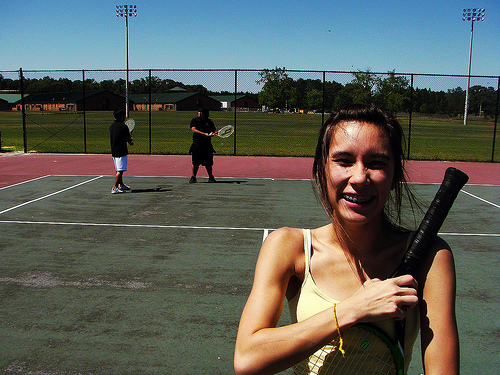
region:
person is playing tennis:
[98, 103, 145, 198]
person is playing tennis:
[196, 102, 249, 189]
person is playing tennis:
[280, 98, 462, 373]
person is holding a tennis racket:
[85, 105, 150, 186]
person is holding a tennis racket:
[190, 101, 242, 197]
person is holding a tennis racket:
[299, 110, 427, 367]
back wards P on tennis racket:
[215, 121, 237, 148]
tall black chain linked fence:
[266, 62, 313, 159]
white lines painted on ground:
[66, 209, 183, 249]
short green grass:
[252, 120, 286, 147]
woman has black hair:
[353, 108, 377, 118]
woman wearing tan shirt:
[306, 300, 315, 315]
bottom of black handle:
[440, 164, 472, 187]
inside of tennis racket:
[348, 359, 363, 373]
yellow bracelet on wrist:
[328, 303, 343, 333]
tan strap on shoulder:
[300, 223, 316, 270]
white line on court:
[175, 213, 203, 238]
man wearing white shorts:
[114, 159, 128, 171]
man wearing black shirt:
[112, 139, 122, 150]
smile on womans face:
[338, 188, 383, 212]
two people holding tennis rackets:
[69, 93, 249, 205]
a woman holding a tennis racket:
[251, 108, 460, 373]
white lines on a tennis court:
[0, 208, 257, 232]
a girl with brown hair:
[298, 90, 404, 247]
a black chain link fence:
[255, 51, 320, 171]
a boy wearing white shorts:
[107, 148, 134, 179]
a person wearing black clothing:
[191, 93, 220, 184]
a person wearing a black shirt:
[105, 116, 135, 153]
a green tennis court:
[30, 198, 250, 325]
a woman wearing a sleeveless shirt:
[262, 226, 384, 334]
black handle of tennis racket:
[382, 168, 474, 276]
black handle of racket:
[401, 161, 478, 275]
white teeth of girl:
[342, 191, 376, 209]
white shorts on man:
[107, 155, 129, 177]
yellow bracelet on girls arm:
[318, 305, 345, 341]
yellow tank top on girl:
[293, 235, 322, 317]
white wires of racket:
[300, 338, 377, 374]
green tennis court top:
[0, 208, 176, 350]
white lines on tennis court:
[0, 161, 100, 241]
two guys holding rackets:
[94, 90, 245, 210]